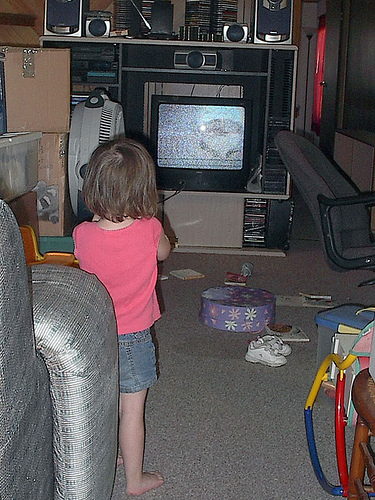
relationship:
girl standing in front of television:
[72, 134, 173, 499] [148, 95, 256, 196]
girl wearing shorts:
[72, 134, 173, 499] [117, 327, 161, 393]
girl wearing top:
[72, 134, 173, 499] [72, 217, 167, 336]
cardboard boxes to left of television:
[0, 44, 72, 239] [148, 95, 256, 196]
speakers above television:
[43, 1, 294, 45] [148, 95, 256, 196]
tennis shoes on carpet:
[243, 334, 292, 368] [111, 184, 374, 499]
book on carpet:
[265, 322, 309, 344] [111, 184, 374, 499]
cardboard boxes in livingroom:
[0, 44, 72, 239] [0, 2, 373, 499]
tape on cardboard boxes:
[24, 50, 36, 77] [0, 44, 72, 239]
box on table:
[2, 130, 43, 202] [10, 191, 42, 255]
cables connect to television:
[159, 178, 188, 210] [148, 95, 256, 196]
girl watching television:
[72, 134, 173, 499] [148, 95, 256, 196]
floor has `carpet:
[111, 183, 374, 499] [111, 184, 374, 499]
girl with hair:
[72, 134, 173, 499] [84, 138, 161, 224]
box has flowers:
[200, 283, 276, 335] [197, 286, 275, 335]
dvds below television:
[241, 196, 270, 249] [148, 95, 256, 196]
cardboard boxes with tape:
[0, 44, 72, 239] [24, 50, 36, 77]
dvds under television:
[241, 196, 270, 249] [148, 95, 256, 196]